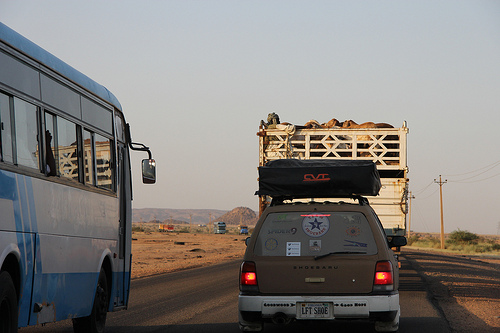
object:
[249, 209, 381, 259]
car window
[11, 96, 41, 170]
window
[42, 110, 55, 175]
window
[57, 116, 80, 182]
window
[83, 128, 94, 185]
window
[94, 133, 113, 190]
window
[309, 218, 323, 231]
star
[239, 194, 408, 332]
car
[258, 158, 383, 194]
bag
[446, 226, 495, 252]
bush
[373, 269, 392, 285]
brake lights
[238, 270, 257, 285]
brake lights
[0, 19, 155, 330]
blue bus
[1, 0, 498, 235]
sky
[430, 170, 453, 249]
two people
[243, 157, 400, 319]
traffic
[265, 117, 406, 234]
traffic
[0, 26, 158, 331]
traffic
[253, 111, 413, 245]
truck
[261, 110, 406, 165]
animals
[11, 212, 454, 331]
freeway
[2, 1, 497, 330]
weather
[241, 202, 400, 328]
back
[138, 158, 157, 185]
mirror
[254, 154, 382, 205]
rack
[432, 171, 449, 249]
pole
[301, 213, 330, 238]
sticker